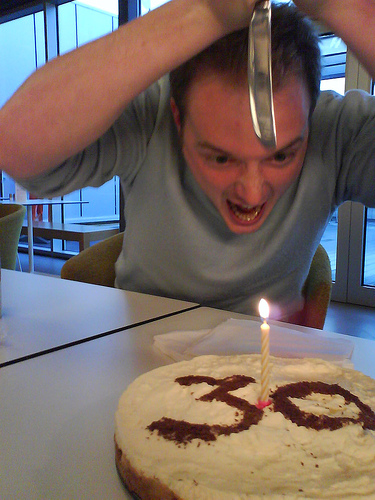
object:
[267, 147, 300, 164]
eye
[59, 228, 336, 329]
chair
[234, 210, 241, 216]
teeth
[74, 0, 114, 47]
window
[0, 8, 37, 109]
window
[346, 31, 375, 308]
door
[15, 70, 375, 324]
gray shirt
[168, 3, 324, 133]
hair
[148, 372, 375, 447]
brown frosting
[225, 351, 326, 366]
white frosting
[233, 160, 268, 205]
nose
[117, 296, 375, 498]
cake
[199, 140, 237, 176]
eye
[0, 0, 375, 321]
man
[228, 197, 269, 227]
mouth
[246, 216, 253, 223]
teeth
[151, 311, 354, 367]
napkin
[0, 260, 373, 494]
table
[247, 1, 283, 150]
knife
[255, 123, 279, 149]
tip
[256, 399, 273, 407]
piece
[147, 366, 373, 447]
number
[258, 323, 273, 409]
candle